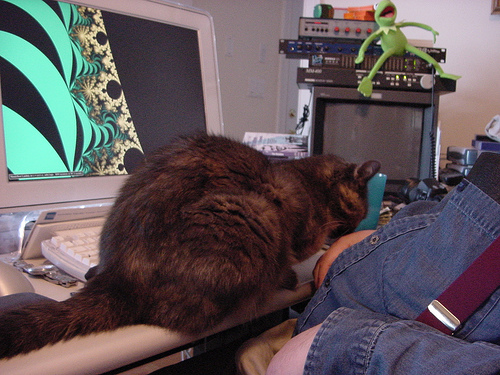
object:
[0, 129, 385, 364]
cat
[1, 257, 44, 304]
computer mouse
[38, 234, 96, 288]
edge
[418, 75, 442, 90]
silver knob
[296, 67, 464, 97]
player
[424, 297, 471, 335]
silver buckle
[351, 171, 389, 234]
blue glass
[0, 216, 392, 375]
desk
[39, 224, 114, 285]
keyboard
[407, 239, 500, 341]
strap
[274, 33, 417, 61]
electronics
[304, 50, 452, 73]
electronics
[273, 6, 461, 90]
stack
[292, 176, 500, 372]
shirt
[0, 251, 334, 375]
counter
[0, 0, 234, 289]
computer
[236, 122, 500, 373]
person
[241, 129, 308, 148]
book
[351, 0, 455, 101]
frog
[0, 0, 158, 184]
design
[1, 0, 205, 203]
monitor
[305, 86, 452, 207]
tv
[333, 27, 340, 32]
knob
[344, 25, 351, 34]
knob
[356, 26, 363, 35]
knob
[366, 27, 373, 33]
knob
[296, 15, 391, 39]
machine